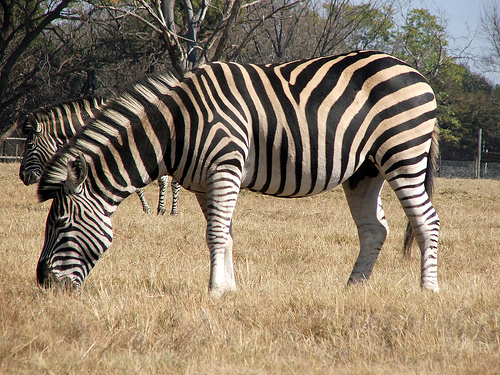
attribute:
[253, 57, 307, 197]
stripe — black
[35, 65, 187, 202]
mane — black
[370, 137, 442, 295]
legs — black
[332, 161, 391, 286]
legs — white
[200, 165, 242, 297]
legs — black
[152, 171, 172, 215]
legs — white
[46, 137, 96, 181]
ear — pointy, white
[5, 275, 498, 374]
grass — dried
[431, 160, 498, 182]
fence — metal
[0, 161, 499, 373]
grass — tan, dead, dry, brown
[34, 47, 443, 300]
zebra — standing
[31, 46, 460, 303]
zebras — black, white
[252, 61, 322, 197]
stripe — black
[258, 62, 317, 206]
stripe — black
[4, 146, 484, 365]
field — large